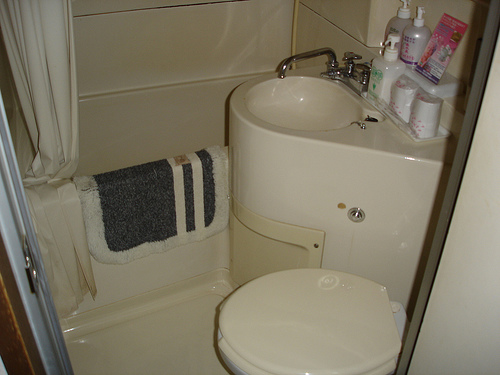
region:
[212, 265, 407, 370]
Toilet with its lid down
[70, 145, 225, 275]
Blue and white bathroom rug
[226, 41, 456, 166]
Small bathroom sink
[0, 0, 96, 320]
Cream colored shower curtain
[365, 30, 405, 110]
Hand soap inside a dispenser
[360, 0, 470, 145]
Several bathroom supplies on a sink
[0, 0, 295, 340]
Empty bathtub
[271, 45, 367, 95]
Metal faucet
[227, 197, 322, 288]
Storage under the sink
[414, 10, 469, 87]
Pink and purple paper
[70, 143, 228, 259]
a bathroom floor mat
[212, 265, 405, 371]
a toilet in an RV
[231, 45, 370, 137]
a fiberglass sink on an RV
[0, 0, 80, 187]
a vinyl shower curtain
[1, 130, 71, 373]
a sliding door frame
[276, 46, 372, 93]
the metal water valves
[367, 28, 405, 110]
a bottle of liquid hand soap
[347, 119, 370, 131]
a chain to the sink stopper pug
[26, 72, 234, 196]
a mini tub in the camper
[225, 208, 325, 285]
access door to the sink pipes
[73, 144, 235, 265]
a white and gray rug hanging on a bath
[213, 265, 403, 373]
a white toilet in a bathroom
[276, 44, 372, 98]
a stainless steel faucet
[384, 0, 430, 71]
two bottle of hand lotion on a counter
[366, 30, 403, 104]
a square bottle of hand soap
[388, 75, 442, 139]
two wrapped plastic cups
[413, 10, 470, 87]
a colorful card popped against the wall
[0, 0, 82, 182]
a white shower drape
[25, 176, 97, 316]
a white towel hanging on the bathtub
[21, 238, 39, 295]
silver hinge of a door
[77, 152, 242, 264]
Black and white fabric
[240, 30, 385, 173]
Small white sink with irtems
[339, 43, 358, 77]
SIlver colored fixture in bathroom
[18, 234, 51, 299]
Small silver door handle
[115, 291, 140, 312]
Part of a cream colored baseboard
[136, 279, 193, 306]
Part of a cream colored baseboard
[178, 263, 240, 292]
Part of a cream colored baseboard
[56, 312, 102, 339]
Part of a cream colored baseboard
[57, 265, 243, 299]
Part of a cream colored baseboard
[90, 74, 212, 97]
Part of a cream colored baseboard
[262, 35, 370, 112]
Silver faucet in sink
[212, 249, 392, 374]
White toilet lid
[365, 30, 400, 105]
White and green soap pump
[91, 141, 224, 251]
Grey and white towel hanging over tub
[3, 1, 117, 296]
White shower curtain tied back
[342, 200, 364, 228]
Silver flush button for toilet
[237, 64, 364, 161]
White round sink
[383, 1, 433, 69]
Set of two white soap pumps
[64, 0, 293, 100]
white tile wall over tub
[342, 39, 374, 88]
Set of two silver handles for faucet